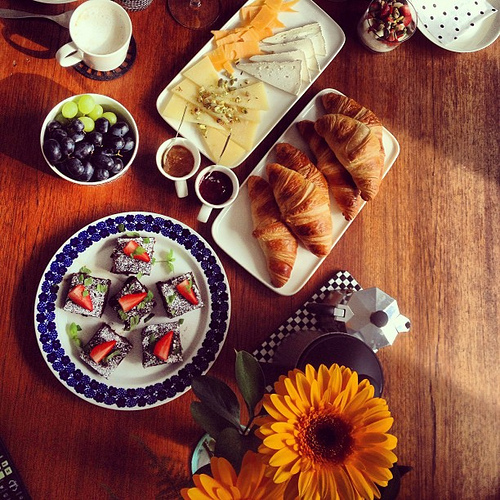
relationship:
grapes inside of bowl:
[47, 95, 134, 181] [97, 95, 137, 128]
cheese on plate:
[168, 55, 269, 167] [259, 84, 296, 141]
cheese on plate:
[248, 22, 329, 95] [259, 84, 296, 141]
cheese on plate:
[205, 2, 299, 73] [259, 84, 296, 141]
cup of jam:
[223, 167, 240, 201] [198, 172, 232, 204]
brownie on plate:
[144, 321, 183, 363] [62, 359, 216, 414]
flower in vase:
[185, 453, 288, 499] [189, 433, 216, 474]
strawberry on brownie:
[71, 284, 92, 314] [81, 275, 110, 317]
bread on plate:
[268, 161, 332, 249] [212, 190, 268, 286]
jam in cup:
[163, 147, 195, 176] [178, 139, 201, 165]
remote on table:
[1, 438, 29, 499] [400, 47, 500, 499]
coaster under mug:
[73, 64, 132, 81] [70, 2, 134, 72]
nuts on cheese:
[203, 92, 221, 111] [168, 55, 269, 167]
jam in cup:
[198, 172, 232, 204] [223, 167, 240, 201]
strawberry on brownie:
[176, 281, 199, 303] [157, 281, 185, 317]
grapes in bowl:
[47, 95, 134, 181] [97, 95, 137, 128]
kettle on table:
[273, 329, 383, 405] [400, 47, 500, 499]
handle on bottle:
[306, 303, 345, 322] [317, 288, 414, 349]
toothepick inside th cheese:
[163, 102, 188, 161] [168, 55, 269, 167]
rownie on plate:
[144, 321, 183, 363] [62, 359, 216, 414]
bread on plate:
[298, 122, 354, 223] [212, 190, 268, 286]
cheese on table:
[168, 55, 269, 167] [400, 47, 500, 499]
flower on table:
[256, 356, 398, 499] [400, 47, 500, 499]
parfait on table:
[359, 2, 417, 53] [400, 47, 500, 499]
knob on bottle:
[374, 312, 387, 326] [317, 288, 414, 349]